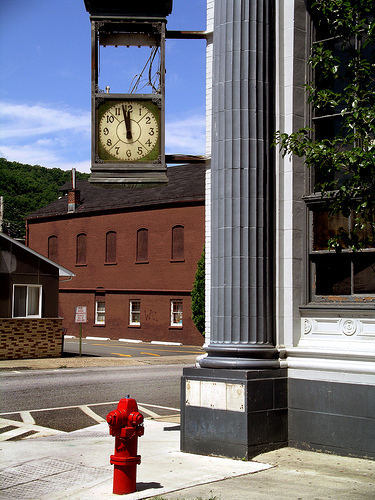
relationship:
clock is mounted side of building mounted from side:
[87, 22, 224, 184] [140, 20, 233, 192]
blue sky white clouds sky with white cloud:
[2, 2, 205, 161] [2, 105, 214, 171]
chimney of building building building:
[65, 189, 79, 215] [17, 209, 207, 348]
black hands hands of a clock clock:
[120, 106, 136, 142] [91, 93, 167, 167]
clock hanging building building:
[86, 7, 170, 188] [203, 3, 375, 446]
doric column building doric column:
[209, 6, 281, 374] [209, 0, 281, 373]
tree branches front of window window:
[273, 7, 374, 259] [301, 3, 375, 318]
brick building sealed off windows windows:
[17, 209, 207, 348] [38, 223, 201, 265]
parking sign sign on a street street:
[73, 306, 91, 353] [65, 340, 201, 360]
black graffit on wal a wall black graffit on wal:
[144, 307, 161, 324] [144, 307, 161, 324]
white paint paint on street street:
[1, 399, 182, 438] [2, 370, 185, 428]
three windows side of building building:
[94, 298, 186, 331] [17, 209, 207, 348]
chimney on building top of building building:
[65, 189, 79, 215] [17, 209, 207, 348]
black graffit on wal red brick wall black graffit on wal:
[142, 306, 162, 340] [144, 307, 161, 324]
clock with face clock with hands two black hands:
[91, 93, 167, 167] [120, 106, 136, 142]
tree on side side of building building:
[191, 252, 209, 344] [203, 3, 375, 446]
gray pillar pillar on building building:
[209, 6, 281, 374] [203, 3, 375, 446]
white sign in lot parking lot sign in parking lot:
[75, 302, 91, 322] [73, 306, 91, 353]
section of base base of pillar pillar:
[181, 378, 250, 417] [209, 6, 281, 374]